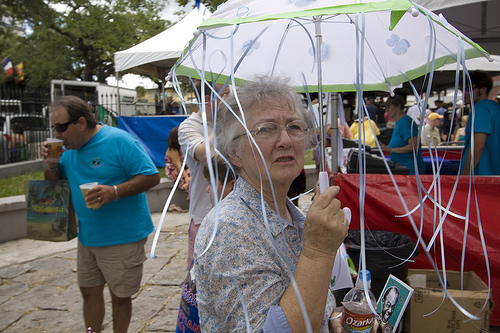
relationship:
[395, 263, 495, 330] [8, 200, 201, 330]
box on ground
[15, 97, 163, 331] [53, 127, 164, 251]
man wearing shirt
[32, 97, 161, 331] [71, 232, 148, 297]
man wearing shorts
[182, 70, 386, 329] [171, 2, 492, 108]
woman holding umbrella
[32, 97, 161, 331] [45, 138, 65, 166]
man sipping beer cup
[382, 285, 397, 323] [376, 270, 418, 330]
man's head on sign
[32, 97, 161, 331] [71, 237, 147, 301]
man wearing shorts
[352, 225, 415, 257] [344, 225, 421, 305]
trash bag in trash can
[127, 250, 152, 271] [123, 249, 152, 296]
flap on pocket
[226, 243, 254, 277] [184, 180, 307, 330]
flowers on shirt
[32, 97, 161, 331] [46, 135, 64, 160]
man drinking from cup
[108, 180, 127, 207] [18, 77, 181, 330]
bracelet on wrist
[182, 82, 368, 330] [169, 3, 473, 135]
woman holding umbrella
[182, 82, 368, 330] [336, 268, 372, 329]
woman holding bottle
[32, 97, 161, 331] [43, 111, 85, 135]
man wearing sunglasses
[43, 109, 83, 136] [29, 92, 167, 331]
glasses are on face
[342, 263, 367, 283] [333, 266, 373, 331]
cap in bottle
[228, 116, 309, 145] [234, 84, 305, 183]
glasses are on face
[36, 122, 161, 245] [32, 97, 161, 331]
shirt on man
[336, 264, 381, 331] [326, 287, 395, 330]
bottle in hands